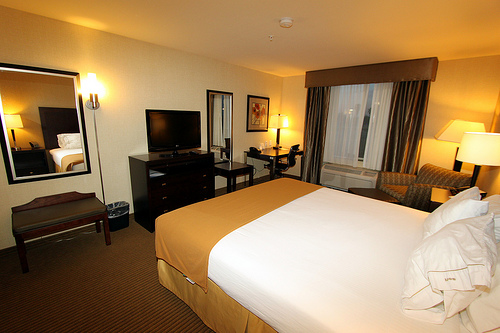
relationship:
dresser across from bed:
[129, 154, 229, 206] [148, 169, 497, 313]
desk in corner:
[240, 146, 304, 186] [237, 60, 322, 182]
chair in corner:
[265, 143, 298, 178] [237, 60, 322, 182]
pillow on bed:
[398, 210, 482, 311] [154, 174, 468, 322]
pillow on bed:
[418, 185, 485, 233] [154, 174, 468, 322]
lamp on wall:
[77, 71, 107, 230] [3, 6, 279, 262]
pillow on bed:
[416, 185, 489, 238] [144, 172, 497, 330]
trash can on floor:
[104, 198, 132, 230] [0, 213, 216, 331]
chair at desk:
[264, 137, 300, 178] [248, 140, 305, 180]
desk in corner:
[248, 140, 305, 180] [250, 57, 317, 189]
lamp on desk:
[267, 111, 285, 154] [240, 146, 304, 186]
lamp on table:
[459, 134, 487, 188] [12, 146, 51, 175]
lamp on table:
[454, 131, 500, 201] [420, 180, 484, 240]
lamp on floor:
[71, 63, 116, 243] [4, 188, 484, 331]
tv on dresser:
[145, 109, 200, 159] [127, 147, 215, 233]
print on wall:
[249, 98, 267, 132] [2, 10, 272, 235]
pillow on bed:
[400, 212, 496, 324] [144, 162, 491, 304]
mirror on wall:
[8, 67, 93, 143] [3, 10, 483, 254]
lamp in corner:
[267, 114, 290, 150] [259, 66, 303, 176]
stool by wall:
[0, 11, 281, 255] [103, 44, 185, 81]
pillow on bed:
[400, 212, 496, 324] [209, 175, 388, 290]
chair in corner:
[364, 154, 471, 211] [420, 50, 484, 220]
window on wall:
[322, 79, 405, 172] [240, 70, 285, 110]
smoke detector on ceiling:
[277, 14, 294, 29] [2, 0, 488, 80]